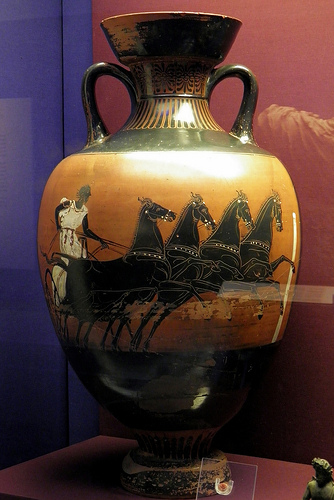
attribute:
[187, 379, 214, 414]
refection — light colored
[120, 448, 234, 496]
base — black, white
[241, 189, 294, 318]
horse — black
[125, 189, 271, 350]
horse — black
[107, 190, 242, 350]
horse — black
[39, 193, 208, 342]
horse — black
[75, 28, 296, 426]
urn — yellow, white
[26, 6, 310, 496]
vase — greek style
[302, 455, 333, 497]
statue — green 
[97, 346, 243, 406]
patch — black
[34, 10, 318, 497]
urn — black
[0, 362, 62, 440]
wall — purple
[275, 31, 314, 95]
wall — clean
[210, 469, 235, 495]
junk — a piece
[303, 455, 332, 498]
figure — green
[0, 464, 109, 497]
table — wooden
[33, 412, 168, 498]
table — brown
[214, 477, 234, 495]
item — white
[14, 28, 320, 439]
vase — is in the picture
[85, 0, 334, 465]
wall — pink, brown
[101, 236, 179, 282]
stripes — brown